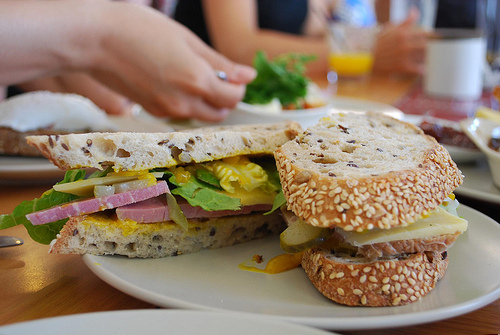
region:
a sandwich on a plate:
[100, 76, 412, 326]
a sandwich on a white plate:
[93, 70, 448, 333]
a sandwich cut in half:
[32, 41, 307, 298]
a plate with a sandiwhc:
[19, 25, 437, 332]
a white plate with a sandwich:
[96, 83, 446, 332]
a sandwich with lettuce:
[74, 86, 421, 334]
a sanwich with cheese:
[123, 97, 465, 318]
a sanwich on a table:
[50, 66, 482, 333]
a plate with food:
[146, 121, 430, 331]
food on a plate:
[60, 65, 374, 323]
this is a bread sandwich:
[261, 96, 469, 308]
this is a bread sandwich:
[29, 106, 289, 284]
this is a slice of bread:
[252, 118, 459, 223]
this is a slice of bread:
[296, 230, 451, 307]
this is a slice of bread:
[46, 199, 259, 263]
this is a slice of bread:
[26, 125, 291, 158]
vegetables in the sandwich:
[169, 170, 232, 225]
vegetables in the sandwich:
[241, 43, 331, 119]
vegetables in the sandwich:
[4, 166, 91, 226]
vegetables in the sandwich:
[218, 160, 275, 210]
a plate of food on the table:
[11, 94, 483, 328]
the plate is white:
[102, 155, 484, 316]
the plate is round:
[77, 140, 492, 332]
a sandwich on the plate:
[40, 86, 452, 290]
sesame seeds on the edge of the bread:
[298, 165, 445, 225]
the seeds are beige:
[320, 168, 441, 221]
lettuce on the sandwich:
[33, 139, 274, 229]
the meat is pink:
[21, 173, 192, 220]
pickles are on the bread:
[267, 208, 345, 261]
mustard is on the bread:
[71, 202, 208, 244]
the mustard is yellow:
[266, 253, 291, 276]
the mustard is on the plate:
[275, 263, 292, 278]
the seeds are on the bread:
[353, 194, 379, 216]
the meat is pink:
[121, 192, 144, 206]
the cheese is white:
[433, 211, 454, 230]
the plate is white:
[184, 276, 226, 301]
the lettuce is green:
[194, 187, 214, 203]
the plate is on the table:
[75, 260, 122, 291]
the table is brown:
[43, 269, 84, 301]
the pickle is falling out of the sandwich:
[291, 227, 318, 250]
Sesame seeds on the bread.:
[336, 187, 357, 212]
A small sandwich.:
[273, 110, 464, 307]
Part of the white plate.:
[178, 278, 213, 295]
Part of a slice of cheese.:
[434, 214, 466, 233]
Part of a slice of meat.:
[27, 210, 74, 221]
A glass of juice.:
[327, 20, 374, 84]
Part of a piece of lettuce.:
[226, 163, 261, 193]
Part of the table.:
[36, 280, 76, 315]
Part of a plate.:
[137, 313, 181, 333]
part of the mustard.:
[271, 258, 287, 272]